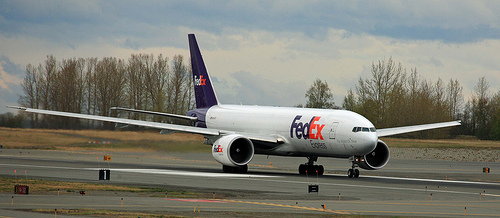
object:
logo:
[289, 114, 324, 139]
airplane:
[6, 34, 461, 177]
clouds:
[260, 27, 317, 63]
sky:
[118, 15, 393, 79]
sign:
[97, 169, 112, 180]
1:
[100, 169, 109, 180]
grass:
[28, 129, 87, 151]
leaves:
[139, 70, 159, 91]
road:
[30, 145, 472, 207]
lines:
[133, 160, 281, 187]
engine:
[211, 134, 254, 166]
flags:
[100, 153, 113, 162]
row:
[76, 70, 137, 111]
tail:
[186, 33, 219, 107]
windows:
[354, 126, 362, 133]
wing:
[5, 105, 222, 136]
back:
[108, 33, 240, 143]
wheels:
[312, 164, 324, 176]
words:
[309, 139, 327, 148]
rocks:
[420, 147, 488, 162]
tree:
[28, 53, 91, 91]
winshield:
[350, 126, 374, 131]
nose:
[331, 116, 384, 159]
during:
[48, 28, 297, 139]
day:
[145, 14, 400, 139]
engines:
[358, 138, 389, 170]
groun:
[141, 124, 327, 177]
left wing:
[375, 119, 463, 137]